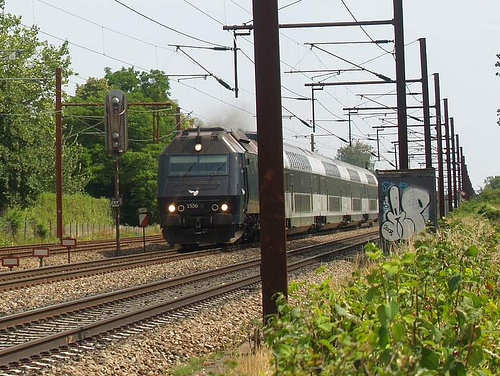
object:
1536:
[186, 202, 199, 209]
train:
[157, 130, 382, 250]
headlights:
[192, 143, 206, 152]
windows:
[169, 155, 226, 175]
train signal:
[105, 89, 129, 157]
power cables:
[0, 3, 461, 199]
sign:
[137, 208, 148, 227]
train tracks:
[4, 219, 380, 365]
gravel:
[2, 253, 255, 376]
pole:
[253, 0, 290, 325]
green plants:
[313, 267, 499, 373]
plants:
[273, 254, 499, 373]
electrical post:
[391, 3, 411, 165]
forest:
[1, 2, 185, 227]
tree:
[69, 63, 179, 217]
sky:
[3, 2, 499, 169]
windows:
[286, 153, 312, 172]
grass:
[190, 344, 269, 374]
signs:
[3, 254, 19, 267]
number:
[185, 202, 199, 209]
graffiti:
[381, 173, 431, 242]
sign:
[380, 167, 437, 243]